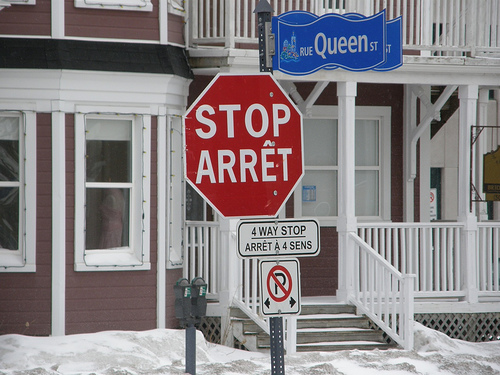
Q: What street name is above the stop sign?
A: Queen.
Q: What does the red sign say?
A: Stop/Arret.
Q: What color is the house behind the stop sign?
A: Purple and white.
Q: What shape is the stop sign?
A: Octagon.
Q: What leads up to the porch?
A: Stairs.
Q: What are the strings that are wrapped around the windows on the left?
A: Christmas lights.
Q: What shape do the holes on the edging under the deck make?
A: Diamonds.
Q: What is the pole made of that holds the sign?
A: Metal.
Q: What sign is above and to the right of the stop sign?
A: Street sign.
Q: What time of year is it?
A: Winter.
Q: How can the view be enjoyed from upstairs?
A: Upper deck.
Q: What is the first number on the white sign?
A: 4.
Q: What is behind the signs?
A: Homes.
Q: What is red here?
A: Stop sign.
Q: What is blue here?
A: The sign.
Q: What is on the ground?
A: Snow.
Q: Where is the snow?
A: On the ground.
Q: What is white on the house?
A: The trim.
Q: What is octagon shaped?
A: The stop sign.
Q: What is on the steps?
A: Snow.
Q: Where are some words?
A: On the signs.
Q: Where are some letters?
A: On the signs.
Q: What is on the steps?
A: Rails.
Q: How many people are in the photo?
A: None.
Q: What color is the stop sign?
A: Red.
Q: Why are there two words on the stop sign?
A: They are different languages.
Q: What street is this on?
A: Queen street.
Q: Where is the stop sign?
A: On the street corner.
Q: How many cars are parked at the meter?
A: None.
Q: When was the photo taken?
A: Daytime.